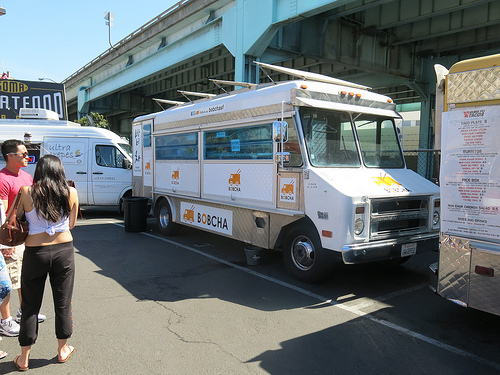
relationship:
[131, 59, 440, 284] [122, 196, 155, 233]
truck beside bin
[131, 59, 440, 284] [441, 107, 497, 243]
truck has a menu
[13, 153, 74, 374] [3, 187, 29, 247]
woman has a purse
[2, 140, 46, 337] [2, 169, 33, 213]
man has on pink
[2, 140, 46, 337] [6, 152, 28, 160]
man has on sunglasses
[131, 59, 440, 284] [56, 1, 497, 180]
truck under overpass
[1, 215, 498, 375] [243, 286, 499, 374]
ground has a shadow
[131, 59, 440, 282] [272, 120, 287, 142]
truck has a mirror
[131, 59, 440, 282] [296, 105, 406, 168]
truck has a windshield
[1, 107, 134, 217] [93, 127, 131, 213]
car has a front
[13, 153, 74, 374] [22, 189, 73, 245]
woman has a back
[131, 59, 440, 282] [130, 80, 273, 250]
truck has a side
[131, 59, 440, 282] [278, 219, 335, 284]
truck has a wheel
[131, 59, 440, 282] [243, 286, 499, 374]
truck has a shadow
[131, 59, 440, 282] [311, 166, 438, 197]
truck has a hood